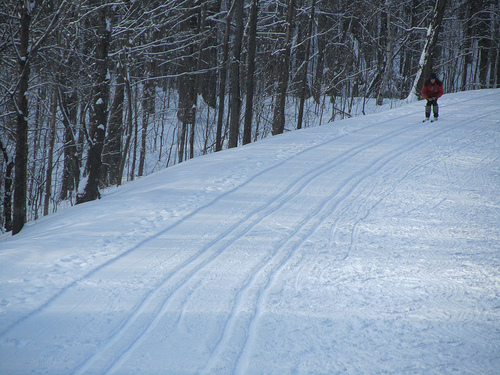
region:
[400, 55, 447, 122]
person walking in white snow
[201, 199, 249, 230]
white snow on the ground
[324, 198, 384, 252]
white snow on the ground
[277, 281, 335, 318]
white snow on the ground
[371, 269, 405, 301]
white snow on the ground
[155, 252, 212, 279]
white snow on the ground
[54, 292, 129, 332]
white snow on the ground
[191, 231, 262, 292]
white snow on the ground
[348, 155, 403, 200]
white snow on the ground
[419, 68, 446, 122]
A person skiing in the snow.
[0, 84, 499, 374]
A snowy ski area.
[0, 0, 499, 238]
An area of snow covered trees.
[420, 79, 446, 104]
A red ski jacket.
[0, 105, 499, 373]
Ski tracks in the snow.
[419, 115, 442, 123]
A pair of skis.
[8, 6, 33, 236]
A brown tree trunk.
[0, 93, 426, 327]
Footprints in the snow.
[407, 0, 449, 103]
A snow covered tree trunk.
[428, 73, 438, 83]
A black ski hat.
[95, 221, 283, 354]
the tracks are in the snow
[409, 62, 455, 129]
the kid is skiing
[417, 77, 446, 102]
the kid is wearing a jacket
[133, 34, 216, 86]
the branches have snow on them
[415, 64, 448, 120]
the kid is wearing skis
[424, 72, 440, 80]
the kid is wearing a cap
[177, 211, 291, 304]
the snow is thick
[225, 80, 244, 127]
the tree trunk is brown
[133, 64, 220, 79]
no leaves are on the branches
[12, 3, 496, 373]
This is a mountain slope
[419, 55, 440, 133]
This is a skier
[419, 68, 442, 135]
Man is riding skis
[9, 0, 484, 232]
Tree line next to slope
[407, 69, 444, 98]
Man has red jacket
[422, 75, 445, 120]
Man is slouching on skis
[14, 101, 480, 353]
Ski tracks within the snow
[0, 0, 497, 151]
Dead trees with snow on them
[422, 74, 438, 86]
Man has black winter cap on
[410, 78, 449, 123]
Man skiing down slope